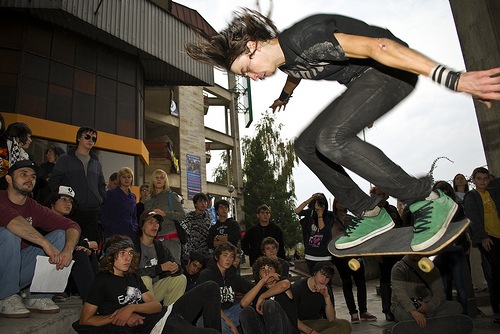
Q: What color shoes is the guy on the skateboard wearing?
A: Green.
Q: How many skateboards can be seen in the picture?
A: Two.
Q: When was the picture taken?
A: In the afternoon.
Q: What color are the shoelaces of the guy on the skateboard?
A: Black.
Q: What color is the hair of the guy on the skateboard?
A: Brown.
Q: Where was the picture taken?
A: A skate park.